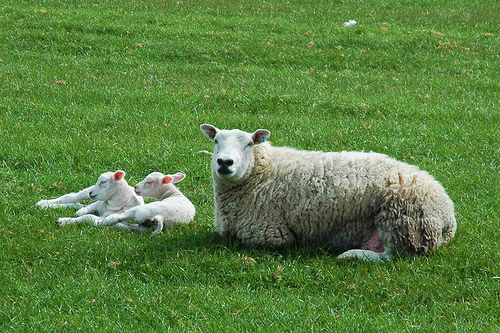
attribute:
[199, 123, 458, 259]
sheep — brown, adult, looking, relaxing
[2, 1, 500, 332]
grass — green, thick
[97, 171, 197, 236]
sheep — white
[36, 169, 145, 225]
sheep — white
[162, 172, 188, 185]
ears — pink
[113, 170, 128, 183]
ear — pink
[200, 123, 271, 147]
ears — white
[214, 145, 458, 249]
fur — thick, light brown, grey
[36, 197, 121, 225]
feets — white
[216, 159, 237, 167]
nose — black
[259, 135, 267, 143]
tag — blue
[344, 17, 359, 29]
plant — small, white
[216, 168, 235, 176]
mouth — black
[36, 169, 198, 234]
sheeps — wooly, white